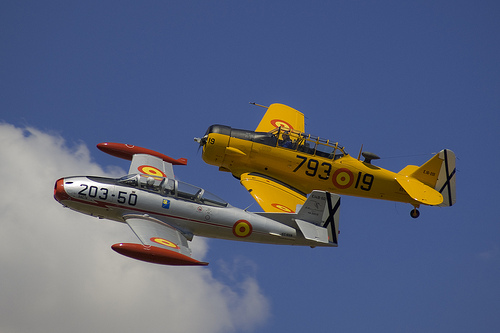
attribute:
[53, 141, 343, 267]
airplane — gray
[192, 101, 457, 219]
airplane — black, yellow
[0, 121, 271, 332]
cloud — fluffy, grey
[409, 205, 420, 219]
landing gear — down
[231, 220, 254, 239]
circle — red color, yellow, yellow colored, red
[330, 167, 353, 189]
circle — red, yellow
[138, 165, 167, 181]
circle — yellow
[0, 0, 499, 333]
sky — blue, cloudy, clear, sunny, blue hue, blue colored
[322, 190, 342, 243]
spot — x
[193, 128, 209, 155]
propeller — rapid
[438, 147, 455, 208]
spot — x